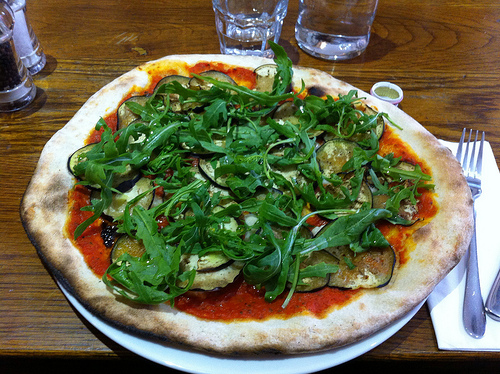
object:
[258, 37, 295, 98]
spinach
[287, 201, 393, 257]
spinach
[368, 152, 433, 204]
spinach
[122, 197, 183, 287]
spinach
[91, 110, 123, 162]
spinach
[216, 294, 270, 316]
sauce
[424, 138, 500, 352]
napkin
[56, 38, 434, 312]
dandelion greens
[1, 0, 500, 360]
table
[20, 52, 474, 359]
crust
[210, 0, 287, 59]
glasses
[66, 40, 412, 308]
vegetable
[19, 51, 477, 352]
pizza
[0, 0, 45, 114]
pepper shaker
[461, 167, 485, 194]
light shining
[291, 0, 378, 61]
glass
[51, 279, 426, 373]
plate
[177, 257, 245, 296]
eggplant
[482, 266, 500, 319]
handle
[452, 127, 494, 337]
fork